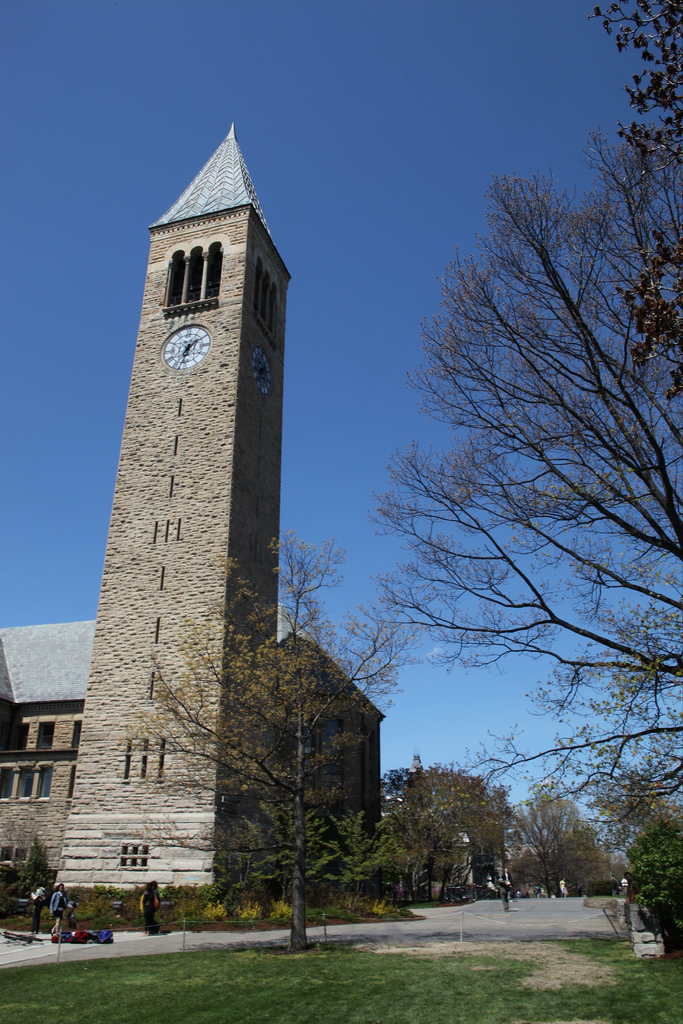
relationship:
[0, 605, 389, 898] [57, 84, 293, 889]
building has tower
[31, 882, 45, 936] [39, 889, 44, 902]
person carries backpack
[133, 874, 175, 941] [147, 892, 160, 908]
person wears shirt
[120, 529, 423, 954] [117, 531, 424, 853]
tree has leaves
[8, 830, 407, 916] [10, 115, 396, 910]
bushes around building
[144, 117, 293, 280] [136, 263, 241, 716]
steeple on tower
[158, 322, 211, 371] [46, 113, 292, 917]
clock on tower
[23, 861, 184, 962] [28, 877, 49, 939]
group of person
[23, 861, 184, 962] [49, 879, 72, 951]
group of person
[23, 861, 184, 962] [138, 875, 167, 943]
group of person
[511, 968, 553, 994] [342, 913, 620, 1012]
patch of dirt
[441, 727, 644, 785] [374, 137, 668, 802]
branch on tree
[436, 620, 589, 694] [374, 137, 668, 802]
branch on tree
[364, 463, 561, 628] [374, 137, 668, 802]
branch on tree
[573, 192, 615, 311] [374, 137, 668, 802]
branch on tree